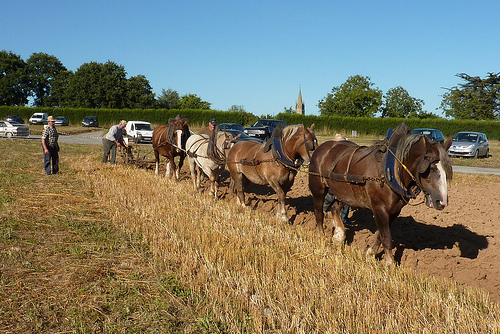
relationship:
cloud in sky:
[194, 20, 351, 81] [162, 7, 332, 46]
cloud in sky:
[0, 0, 498, 107] [134, 10, 403, 37]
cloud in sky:
[0, 0, 498, 107] [211, 14, 400, 59]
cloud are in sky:
[0, 0, 498, 107] [158, 31, 224, 101]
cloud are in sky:
[0, 0, 498, 107] [259, 13, 353, 64]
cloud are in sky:
[0, 0, 498, 107] [208, 8, 333, 48]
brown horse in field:
[228, 118, 322, 224] [4, 132, 493, 332]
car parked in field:
[447, 131, 490, 158] [4, 132, 493, 332]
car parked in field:
[54, 116, 69, 126] [4, 132, 493, 332]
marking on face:
[434, 155, 452, 207] [411, 132, 456, 212]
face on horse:
[411, 132, 456, 212] [304, 121, 461, 268]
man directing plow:
[97, 117, 130, 164] [120, 141, 156, 167]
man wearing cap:
[40, 116, 62, 176] [46, 116, 56, 122]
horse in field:
[304, 121, 461, 268] [22, 139, 459, 329]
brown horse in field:
[226, 122, 320, 225] [22, 139, 459, 329]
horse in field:
[179, 124, 241, 201] [22, 139, 459, 329]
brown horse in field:
[152, 118, 191, 180] [22, 139, 459, 329]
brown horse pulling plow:
[152, 118, 191, 180] [117, 137, 151, 167]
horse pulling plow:
[185, 132, 242, 199] [117, 137, 151, 167]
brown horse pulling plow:
[226, 122, 320, 225] [117, 137, 151, 167]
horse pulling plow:
[309, 132, 454, 266] [117, 137, 151, 167]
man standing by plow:
[101, 119, 127, 164] [119, 132, 153, 166]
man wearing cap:
[38, 112, 64, 175] [43, 113, 58, 126]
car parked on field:
[449, 129, 491, 159] [0, 130, 500, 334]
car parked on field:
[409, 126, 444, 140] [0, 130, 500, 334]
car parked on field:
[124, 120, 154, 143] [0, 130, 500, 334]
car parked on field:
[81, 113, 99, 126] [0, 130, 500, 334]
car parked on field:
[0, 118, 31, 138] [0, 130, 500, 334]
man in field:
[40, 116, 62, 176] [4, 132, 493, 332]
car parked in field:
[121, 118, 164, 157] [4, 132, 493, 332]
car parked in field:
[29, 112, 48, 125] [25, 111, 107, 142]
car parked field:
[447, 131, 490, 158] [11, 111, 498, 326]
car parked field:
[124, 120, 154, 143] [11, 111, 498, 326]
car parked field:
[81, 116, 99, 127] [11, 111, 498, 326]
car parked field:
[48, 114, 68, 129] [11, 111, 498, 326]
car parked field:
[27, 110, 46, 122] [11, 111, 498, 326]